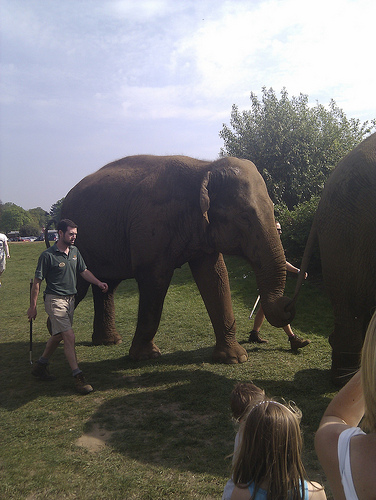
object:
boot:
[290, 333, 310, 351]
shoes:
[72, 373, 93, 393]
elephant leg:
[187, 251, 248, 363]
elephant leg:
[129, 269, 172, 360]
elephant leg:
[90, 278, 122, 346]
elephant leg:
[46, 279, 90, 335]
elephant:
[44, 154, 296, 366]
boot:
[71, 372, 94, 394]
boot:
[32, 359, 57, 381]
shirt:
[34, 240, 87, 296]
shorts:
[43, 287, 76, 336]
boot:
[247, 328, 271, 342]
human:
[247, 218, 312, 351]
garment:
[336, 422, 367, 498]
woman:
[313, 307, 375, 499]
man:
[27, 218, 109, 394]